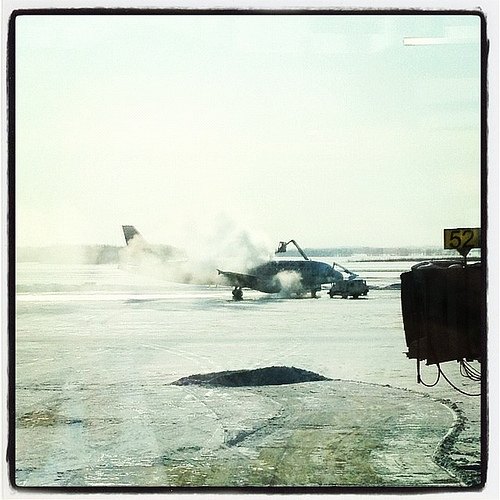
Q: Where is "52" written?
A: On yellow sign.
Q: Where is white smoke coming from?
A: Airplane.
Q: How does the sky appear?
A: Overcast.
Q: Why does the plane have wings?
A: To fly.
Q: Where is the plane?
A: On a runway.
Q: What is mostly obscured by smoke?
A: Small plane.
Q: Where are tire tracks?
A: On the runway.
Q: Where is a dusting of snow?
A: On the ground.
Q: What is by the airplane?
A: The cloud of smoke.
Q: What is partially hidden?
A: The aircraft.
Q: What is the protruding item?
A: The piece of luggage.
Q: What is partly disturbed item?
A: The dirt.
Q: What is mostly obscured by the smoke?
A: The airplane.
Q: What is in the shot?
A: The pile of ash.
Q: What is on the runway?
A: The airplane.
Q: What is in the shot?
A: Airport gate number 52.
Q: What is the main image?
A: Airplane.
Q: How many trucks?
A: One.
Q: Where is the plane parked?
A: On runway.